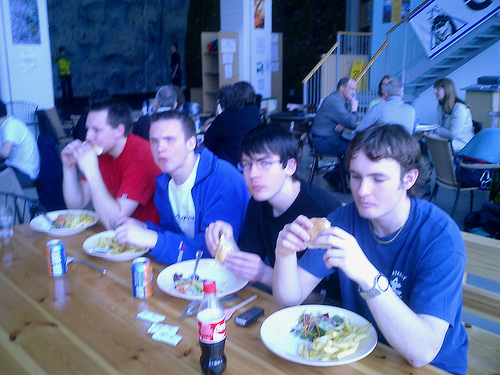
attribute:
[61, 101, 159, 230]
guy — lightskinned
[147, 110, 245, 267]
guy — lightskinned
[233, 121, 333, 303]
guy — lightskinned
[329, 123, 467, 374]
guy — lightskinned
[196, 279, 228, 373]
bottle — plastic, coke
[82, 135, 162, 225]
t-shirt — red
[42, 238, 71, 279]
can — soda, aluminum, blue, orange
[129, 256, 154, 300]
can — soda, aluminum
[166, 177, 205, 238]
t-shirt — white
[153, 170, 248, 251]
jacket — blue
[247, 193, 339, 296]
t-shirt — black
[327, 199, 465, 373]
t-shirt — blue, short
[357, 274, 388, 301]
watch — silver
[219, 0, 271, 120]
column — white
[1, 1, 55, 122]
column — white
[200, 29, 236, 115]
shelving — brown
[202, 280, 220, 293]
cap — red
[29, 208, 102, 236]
bowl — white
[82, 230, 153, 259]
bowl — white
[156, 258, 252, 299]
bowl — white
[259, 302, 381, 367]
bowl — white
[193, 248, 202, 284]
utensil — metal, silver